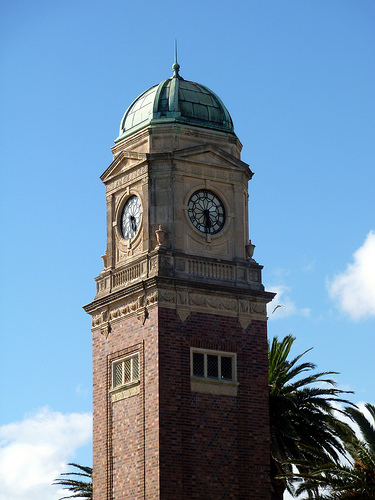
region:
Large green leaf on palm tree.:
[270, 340, 283, 391]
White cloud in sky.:
[327, 253, 372, 348]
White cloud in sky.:
[16, 388, 58, 472]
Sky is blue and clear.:
[22, 273, 54, 335]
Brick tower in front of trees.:
[127, 367, 227, 469]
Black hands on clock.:
[199, 204, 216, 236]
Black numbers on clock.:
[192, 193, 227, 230]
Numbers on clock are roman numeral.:
[192, 201, 220, 235]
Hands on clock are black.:
[121, 216, 140, 231]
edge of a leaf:
[308, 435, 309, 436]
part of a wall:
[215, 456, 221, 467]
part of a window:
[217, 367, 228, 387]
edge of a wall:
[154, 472, 155, 477]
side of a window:
[204, 363, 207, 364]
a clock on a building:
[88, 158, 263, 280]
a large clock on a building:
[88, 166, 219, 260]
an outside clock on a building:
[115, 178, 241, 259]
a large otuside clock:
[107, 175, 265, 283]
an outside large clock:
[113, 183, 242, 286]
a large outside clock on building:
[117, 179, 267, 271]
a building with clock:
[104, 169, 237, 252]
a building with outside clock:
[111, 169, 343, 362]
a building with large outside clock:
[99, 178, 215, 285]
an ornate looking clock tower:
[95, 141, 263, 292]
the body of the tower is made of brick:
[78, 287, 288, 498]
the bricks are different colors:
[79, 285, 277, 497]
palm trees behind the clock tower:
[268, 329, 372, 497]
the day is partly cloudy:
[4, 335, 89, 458]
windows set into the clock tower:
[105, 345, 145, 399]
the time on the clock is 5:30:
[179, 179, 232, 242]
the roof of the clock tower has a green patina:
[104, 31, 247, 151]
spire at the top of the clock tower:
[161, 31, 191, 79]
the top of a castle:
[140, 30, 219, 86]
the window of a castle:
[103, 346, 157, 394]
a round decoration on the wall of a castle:
[108, 191, 149, 253]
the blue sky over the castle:
[13, 5, 367, 95]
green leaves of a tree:
[272, 326, 373, 468]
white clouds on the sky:
[344, 242, 374, 312]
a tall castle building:
[72, 7, 318, 452]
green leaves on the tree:
[304, 388, 316, 411]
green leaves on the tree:
[324, 443, 354, 481]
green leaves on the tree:
[294, 415, 310, 455]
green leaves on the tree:
[303, 375, 336, 430]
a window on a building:
[109, 363, 123, 390]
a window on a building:
[119, 357, 129, 384]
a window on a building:
[130, 356, 140, 384]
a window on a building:
[196, 347, 205, 381]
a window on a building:
[205, 351, 218, 375]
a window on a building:
[220, 353, 232, 379]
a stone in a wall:
[175, 220, 186, 237]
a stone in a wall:
[174, 234, 188, 251]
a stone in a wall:
[234, 190, 245, 206]